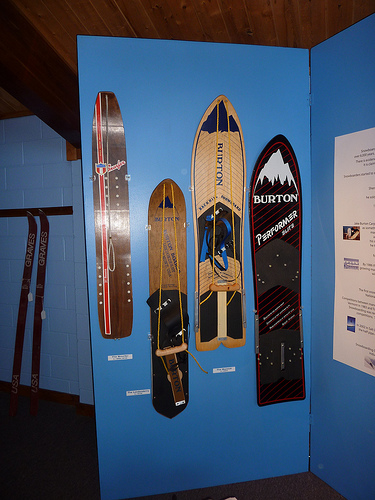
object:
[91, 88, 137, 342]
skateboard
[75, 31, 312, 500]
board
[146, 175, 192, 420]
skateboard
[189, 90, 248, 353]
skateboard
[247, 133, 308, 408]
skateboard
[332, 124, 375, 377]
paper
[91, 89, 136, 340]
skateboards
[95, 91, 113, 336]
line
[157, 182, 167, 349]
thread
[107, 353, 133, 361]
label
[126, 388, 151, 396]
label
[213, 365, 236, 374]
label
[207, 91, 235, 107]
nose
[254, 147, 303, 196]
mountain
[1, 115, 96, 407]
wall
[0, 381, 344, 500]
ground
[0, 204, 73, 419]
ski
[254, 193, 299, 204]
burton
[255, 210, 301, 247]
performer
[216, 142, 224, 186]
ripton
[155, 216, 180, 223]
barton